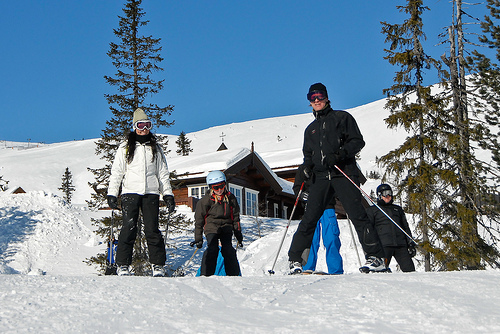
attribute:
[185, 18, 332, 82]
sky — blue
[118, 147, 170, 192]
jacket — black, white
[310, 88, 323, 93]
hat — black, white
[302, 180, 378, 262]
pants — black, blue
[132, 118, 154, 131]
goggles — red, white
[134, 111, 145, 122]
helmet — white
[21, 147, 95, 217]
hill — white, snowy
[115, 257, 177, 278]
boots — white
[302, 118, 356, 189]
coat — black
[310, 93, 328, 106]
sunglasses — black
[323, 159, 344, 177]
gloves — black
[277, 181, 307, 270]
poles — ski